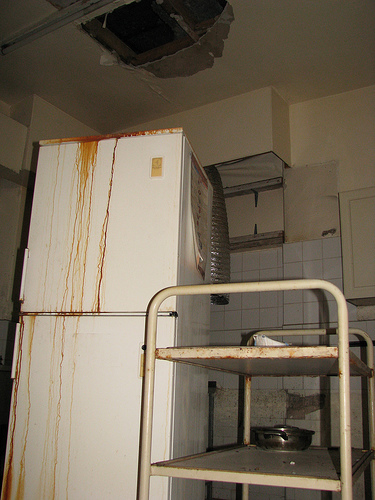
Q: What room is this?
A: Kitchen.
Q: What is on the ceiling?
A: Large hole.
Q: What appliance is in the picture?
A: Refrigerator.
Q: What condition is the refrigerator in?
A: Dirty.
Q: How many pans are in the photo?
A: One.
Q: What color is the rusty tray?
A: Tan.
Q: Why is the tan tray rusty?
A: Moisture and water have corroded it.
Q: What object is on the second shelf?
A: A pan.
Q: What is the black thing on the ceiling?
A: A hole.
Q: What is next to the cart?
A: Refrigerator.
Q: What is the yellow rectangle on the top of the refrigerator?
A: A sticker.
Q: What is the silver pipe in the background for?
A: It's a vent.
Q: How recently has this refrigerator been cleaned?
A: Not recently.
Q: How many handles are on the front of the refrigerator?
A: Two.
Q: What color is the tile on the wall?
A: White.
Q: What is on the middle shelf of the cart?
A: A pan.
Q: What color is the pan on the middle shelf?
A: Silver.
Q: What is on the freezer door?
A: Rust.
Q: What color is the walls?
A: It is White.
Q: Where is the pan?
A: On a cart.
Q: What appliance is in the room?
A: A refrigerator.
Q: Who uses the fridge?
A: People.